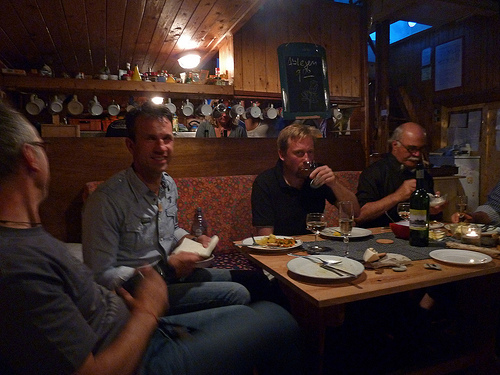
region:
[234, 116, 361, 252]
A man drinking from a glass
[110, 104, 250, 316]
A man holding a napkin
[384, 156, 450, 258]
A wine bottle on a table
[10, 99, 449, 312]
Four men at a resturant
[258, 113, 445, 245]
Two men sitting at a table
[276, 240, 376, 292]
A white plate on a table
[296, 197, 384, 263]
Two wine glasses on a table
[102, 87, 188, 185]
The head of a man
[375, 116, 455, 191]
The head of a man with a moustache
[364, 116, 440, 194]
The head of a bald man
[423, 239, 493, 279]
empty plate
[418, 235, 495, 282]
empty plate on table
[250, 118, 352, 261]
man sitting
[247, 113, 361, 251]
man sitting drinking from glass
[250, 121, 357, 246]
man sitting on cushioned bench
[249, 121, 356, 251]
man sitting on cushioned bench at table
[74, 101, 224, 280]
man wearing light blue long sleeve shirt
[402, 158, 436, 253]
wine bottle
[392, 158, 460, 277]
wine bottle on table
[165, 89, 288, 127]
coffee mugs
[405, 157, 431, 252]
A green wine bottle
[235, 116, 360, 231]
A man sipping from a glass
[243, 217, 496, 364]
A wooden dining table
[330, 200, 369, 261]
A clear champagne glass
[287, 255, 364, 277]
A fork and knife on a plate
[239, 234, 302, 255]
A plate of food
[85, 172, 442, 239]
A floral bench back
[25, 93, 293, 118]
A row of hanging mugs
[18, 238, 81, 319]
Man wearing gray shirt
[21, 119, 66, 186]
Glasses on man's head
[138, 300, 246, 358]
Man wearing blue jeans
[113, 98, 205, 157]
Man has dark hair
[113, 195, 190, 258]
Man wearing button down shirt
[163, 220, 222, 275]
Man holding napkin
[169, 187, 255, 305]
Man wearing blue jeans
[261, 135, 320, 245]
Man wearing black shirt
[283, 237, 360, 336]
Silverware on top of white plate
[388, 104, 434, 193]
Man has bald head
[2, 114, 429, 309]
People sitting at a table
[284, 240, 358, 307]
An empty plate on the table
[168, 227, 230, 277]
A man holding a napkin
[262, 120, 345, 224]
a man drinking his drink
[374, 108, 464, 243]
A man eating his food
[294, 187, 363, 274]
Whine glasses on the table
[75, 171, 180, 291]
He is wearing a blue shirt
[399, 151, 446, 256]
A bottle of whine on the table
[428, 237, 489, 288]
The plate is white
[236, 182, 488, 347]
The table is brown